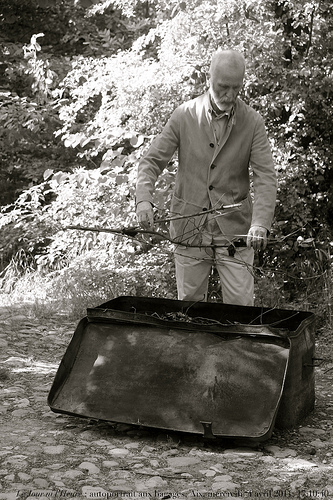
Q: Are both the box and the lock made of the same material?
A: Yes, both the box and the lock are made of metal.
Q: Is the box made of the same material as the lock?
A: Yes, both the box and the lock are made of metal.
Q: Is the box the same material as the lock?
A: Yes, both the box and the lock are made of metal.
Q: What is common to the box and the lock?
A: The material, both the box and the lock are metallic.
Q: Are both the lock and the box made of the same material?
A: Yes, both the lock and the box are made of metal.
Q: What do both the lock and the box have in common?
A: The material, both the lock and the box are metallic.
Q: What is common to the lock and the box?
A: The material, both the lock and the box are metallic.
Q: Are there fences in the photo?
A: No, there are no fences.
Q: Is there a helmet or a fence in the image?
A: No, there are no fences or helmets.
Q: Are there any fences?
A: No, there are no fences.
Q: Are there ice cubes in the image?
A: No, there are no ice cubes.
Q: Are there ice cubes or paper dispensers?
A: No, there are no ice cubes or paper dispensers.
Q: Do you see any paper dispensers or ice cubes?
A: No, there are no ice cubes or paper dispensers.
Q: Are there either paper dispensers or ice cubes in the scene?
A: No, there are no ice cubes or paper dispensers.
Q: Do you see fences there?
A: No, there are no fences.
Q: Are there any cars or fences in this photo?
A: No, there are no fences or cars.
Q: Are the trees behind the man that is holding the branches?
A: Yes, the trees are behind the man.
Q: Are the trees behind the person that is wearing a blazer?
A: Yes, the trees are behind the man.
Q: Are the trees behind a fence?
A: No, the trees are behind the man.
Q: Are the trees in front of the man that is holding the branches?
A: No, the trees are behind the man.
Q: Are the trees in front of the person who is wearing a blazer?
A: No, the trees are behind the man.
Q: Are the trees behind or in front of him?
A: The trees are behind the man.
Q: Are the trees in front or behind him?
A: The trees are behind the man.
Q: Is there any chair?
A: No, there are no chairs.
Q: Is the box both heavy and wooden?
A: No, the box is heavy but metallic.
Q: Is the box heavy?
A: Yes, the box is heavy.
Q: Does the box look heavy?
A: Yes, the box is heavy.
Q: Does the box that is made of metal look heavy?
A: Yes, the box is heavy.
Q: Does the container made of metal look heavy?
A: Yes, the box is heavy.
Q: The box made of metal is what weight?
A: The box is heavy.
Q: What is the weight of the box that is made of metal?
A: The box is heavy.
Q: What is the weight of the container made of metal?
A: The box is heavy.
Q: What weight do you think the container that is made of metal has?
A: The box has heavy weight.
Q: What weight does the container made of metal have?
A: The box has heavy weight.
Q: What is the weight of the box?
A: The box is heavy.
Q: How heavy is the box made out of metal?
A: The box is heavy.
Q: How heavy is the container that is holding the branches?
A: The box is heavy.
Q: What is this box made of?
A: The box is made of metal.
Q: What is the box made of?
A: The box is made of metal.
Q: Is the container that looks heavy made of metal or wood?
A: The box is made of metal.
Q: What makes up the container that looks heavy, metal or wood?
A: The box is made of metal.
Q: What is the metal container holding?
A: The box is holding the branches.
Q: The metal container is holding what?
A: The box is holding the branches.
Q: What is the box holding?
A: The box is holding the branches.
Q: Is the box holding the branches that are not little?
A: Yes, the box is holding the branches.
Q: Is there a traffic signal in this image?
A: No, there are no traffic lights.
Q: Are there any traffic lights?
A: No, there are no traffic lights.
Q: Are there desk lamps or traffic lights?
A: No, there are no traffic lights or desk lamps.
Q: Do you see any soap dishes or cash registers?
A: No, there are no cash registers or soap dishes.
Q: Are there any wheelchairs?
A: No, there are no wheelchairs.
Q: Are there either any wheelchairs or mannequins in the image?
A: No, there are no wheelchairs or mannequins.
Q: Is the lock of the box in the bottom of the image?
A: Yes, the lock is in the bottom of the image.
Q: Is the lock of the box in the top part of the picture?
A: No, the lock is in the bottom of the image.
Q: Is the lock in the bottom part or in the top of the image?
A: The lock is in the bottom of the image.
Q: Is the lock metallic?
A: Yes, the lock is metallic.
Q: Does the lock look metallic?
A: Yes, the lock is metallic.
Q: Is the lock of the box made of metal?
A: Yes, the lock is made of metal.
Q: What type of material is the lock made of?
A: The lock is made of metal.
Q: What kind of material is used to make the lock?
A: The lock is made of metal.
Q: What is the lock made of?
A: The lock is made of metal.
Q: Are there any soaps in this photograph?
A: No, there are no soaps.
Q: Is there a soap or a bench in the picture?
A: No, there are no soaps or benches.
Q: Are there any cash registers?
A: No, there are no cash registers.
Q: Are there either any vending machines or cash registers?
A: No, there are no cash registers or vending machines.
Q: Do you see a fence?
A: No, there are no fences.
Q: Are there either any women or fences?
A: No, there are no fences or women.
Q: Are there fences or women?
A: No, there are no fences or women.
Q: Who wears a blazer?
A: The man wears a blazer.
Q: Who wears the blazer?
A: The man wears a blazer.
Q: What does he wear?
A: The man wears a blazer.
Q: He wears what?
A: The man wears a blazer.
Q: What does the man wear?
A: The man wears a blazer.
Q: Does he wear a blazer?
A: Yes, the man wears a blazer.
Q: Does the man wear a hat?
A: No, the man wears a blazer.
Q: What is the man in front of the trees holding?
A: The man is holding the branches.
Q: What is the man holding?
A: The man is holding the branches.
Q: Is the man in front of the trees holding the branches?
A: Yes, the man is holding the branches.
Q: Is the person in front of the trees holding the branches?
A: Yes, the man is holding the branches.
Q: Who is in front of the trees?
A: The man is in front of the trees.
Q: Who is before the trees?
A: The man is in front of the trees.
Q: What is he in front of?
A: The man is in front of the trees.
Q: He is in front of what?
A: The man is in front of the trees.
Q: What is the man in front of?
A: The man is in front of the trees.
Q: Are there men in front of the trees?
A: Yes, there is a man in front of the trees.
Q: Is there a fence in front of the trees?
A: No, there is a man in front of the trees.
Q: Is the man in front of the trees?
A: Yes, the man is in front of the trees.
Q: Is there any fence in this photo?
A: No, there are no fences.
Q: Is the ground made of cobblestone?
A: Yes, the ground is made of cobblestone.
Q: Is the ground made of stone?
A: No, the ground is made of cobblestone.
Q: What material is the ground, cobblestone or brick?
A: The ground is made of cobblestone.